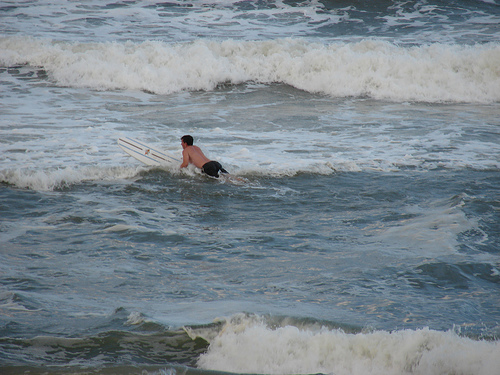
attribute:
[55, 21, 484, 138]
wave — small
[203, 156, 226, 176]
shorts — black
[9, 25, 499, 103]
foam — white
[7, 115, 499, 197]
foam — white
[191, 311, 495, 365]
foam — white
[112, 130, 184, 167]
surfboard — white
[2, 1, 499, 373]
water — rippled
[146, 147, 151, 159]
logo — small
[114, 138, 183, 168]
boad — white 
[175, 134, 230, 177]
man — shirtless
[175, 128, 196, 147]
hair — brown, short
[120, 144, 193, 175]
stripe — blue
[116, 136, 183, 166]
stripe — red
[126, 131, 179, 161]
stripe — blue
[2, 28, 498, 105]
sea foam — white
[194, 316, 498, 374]
sea foam — white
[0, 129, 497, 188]
sea foam — white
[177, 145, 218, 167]
shirt — bare